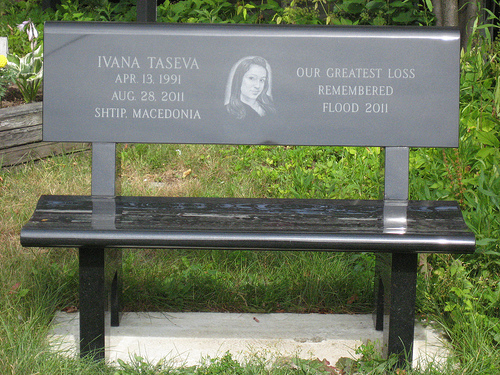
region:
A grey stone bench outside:
[21, 16, 480, 365]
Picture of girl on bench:
[218, 52, 288, 124]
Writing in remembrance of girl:
[87, 49, 420, 121]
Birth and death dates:
[108, 70, 190, 107]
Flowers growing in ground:
[0, 14, 46, 120]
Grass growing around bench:
[3, 252, 497, 372]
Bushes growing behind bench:
[418, 42, 493, 355]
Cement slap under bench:
[37, 291, 464, 373]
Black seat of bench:
[18, 189, 478, 254]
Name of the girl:
[91, 50, 205, 73]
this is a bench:
[91, 196, 408, 248]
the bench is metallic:
[156, 195, 364, 242]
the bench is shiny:
[381, 200, 429, 241]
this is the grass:
[208, 253, 333, 290]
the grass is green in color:
[240, 274, 346, 299]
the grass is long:
[242, 251, 331, 296]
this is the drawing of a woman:
[218, 59, 278, 124]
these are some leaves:
[474, 84, 499, 171]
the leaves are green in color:
[473, 130, 496, 182]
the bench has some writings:
[308, 66, 408, 127]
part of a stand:
[364, 300, 412, 349]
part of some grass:
[438, 293, 491, 364]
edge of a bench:
[299, 236, 358, 255]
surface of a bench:
[251, 205, 301, 239]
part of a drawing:
[238, 70, 264, 100]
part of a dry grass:
[143, 162, 200, 188]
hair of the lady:
[224, 89, 245, 114]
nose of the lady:
[251, 78, 263, 91]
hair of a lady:
[226, 89, 243, 115]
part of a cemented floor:
[243, 322, 286, 351]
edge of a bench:
[243, 227, 315, 253]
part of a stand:
[381, 287, 416, 343]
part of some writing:
[129, 60, 191, 120]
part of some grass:
[450, 290, 482, 339]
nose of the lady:
[248, 78, 264, 98]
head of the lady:
[248, 64, 260, 78]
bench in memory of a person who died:
[31, 2, 472, 314]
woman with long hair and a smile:
[217, 45, 287, 126]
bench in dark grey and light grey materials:
[21, 11, 482, 363]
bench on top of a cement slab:
[1, 20, 456, 366]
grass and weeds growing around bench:
[1, 135, 496, 365]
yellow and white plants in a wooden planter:
[0, 15, 40, 170]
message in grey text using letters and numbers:
[285, 50, 425, 125]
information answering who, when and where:
[85, 41, 212, 126]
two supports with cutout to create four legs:
[57, 250, 447, 366]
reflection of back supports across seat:
[75, 145, 435, 245]